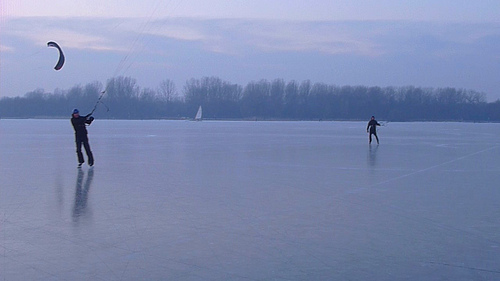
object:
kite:
[46, 40, 65, 70]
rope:
[90, 0, 180, 118]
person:
[70, 108, 95, 168]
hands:
[86, 113, 94, 122]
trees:
[0, 75, 497, 120]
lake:
[0, 120, 499, 280]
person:
[366, 116, 381, 144]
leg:
[83, 141, 94, 163]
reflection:
[70, 166, 95, 223]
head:
[72, 108, 79, 118]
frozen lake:
[171, 119, 500, 280]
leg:
[369, 133, 372, 142]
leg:
[374, 134, 379, 143]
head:
[370, 116, 375, 121]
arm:
[367, 121, 371, 131]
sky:
[0, 0, 499, 28]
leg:
[75, 140, 85, 163]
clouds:
[84, 14, 430, 41]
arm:
[71, 116, 89, 126]